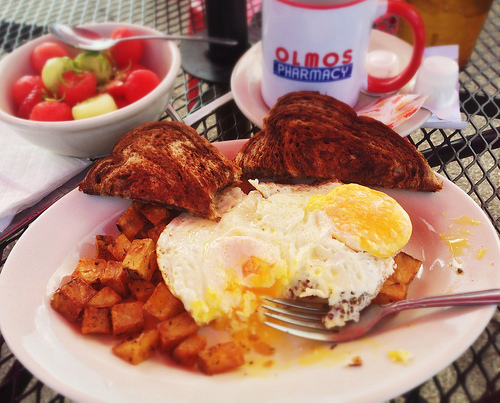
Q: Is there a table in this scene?
A: Yes, there is a table.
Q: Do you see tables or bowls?
A: Yes, there is a table.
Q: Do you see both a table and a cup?
A: Yes, there are both a table and a cup.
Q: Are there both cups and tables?
A: Yes, there are both a table and a cup.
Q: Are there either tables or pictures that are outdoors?
A: Yes, the table is outdoors.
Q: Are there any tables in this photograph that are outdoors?
A: Yes, there is a table that is outdoors.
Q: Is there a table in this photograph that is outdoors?
A: Yes, there is a table that is outdoors.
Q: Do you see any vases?
A: No, there are no vases.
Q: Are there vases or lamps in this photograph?
A: No, there are no vases or lamps.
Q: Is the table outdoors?
A: Yes, the table is outdoors.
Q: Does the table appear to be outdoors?
A: Yes, the table is outdoors.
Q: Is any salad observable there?
A: Yes, there is salad.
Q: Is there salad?
A: Yes, there is salad.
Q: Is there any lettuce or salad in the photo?
A: Yes, there is salad.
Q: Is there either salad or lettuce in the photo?
A: Yes, there is salad.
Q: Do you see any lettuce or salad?
A: Yes, there is salad.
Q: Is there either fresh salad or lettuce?
A: Yes, there is fresh salad.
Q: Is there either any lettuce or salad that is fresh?
A: Yes, the salad is fresh.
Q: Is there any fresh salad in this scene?
A: Yes, there is fresh salad.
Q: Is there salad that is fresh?
A: Yes, there is salad that is fresh.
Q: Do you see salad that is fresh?
A: Yes, there is salad that is fresh.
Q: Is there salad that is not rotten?
A: Yes, there is fresh salad.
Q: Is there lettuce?
A: No, there is no lettuce.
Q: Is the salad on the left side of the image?
A: Yes, the salad is on the left of the image.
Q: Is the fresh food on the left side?
A: Yes, the salad is on the left of the image.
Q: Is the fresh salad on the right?
A: No, the salad is on the left of the image.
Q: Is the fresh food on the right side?
A: No, the salad is on the left of the image.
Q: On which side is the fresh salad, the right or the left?
A: The salad is on the left of the image.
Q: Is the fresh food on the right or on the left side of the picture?
A: The salad is on the left of the image.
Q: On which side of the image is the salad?
A: The salad is on the left of the image.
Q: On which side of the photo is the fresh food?
A: The salad is on the left of the image.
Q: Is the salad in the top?
A: Yes, the salad is in the top of the image.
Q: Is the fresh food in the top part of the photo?
A: Yes, the salad is in the top of the image.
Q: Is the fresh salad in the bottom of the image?
A: No, the salad is in the top of the image.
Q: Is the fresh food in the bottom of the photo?
A: No, the salad is in the top of the image.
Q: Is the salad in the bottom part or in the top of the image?
A: The salad is in the top of the image.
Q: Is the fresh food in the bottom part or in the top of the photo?
A: The salad is in the top of the image.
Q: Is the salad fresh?
A: Yes, the salad is fresh.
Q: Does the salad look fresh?
A: Yes, the salad is fresh.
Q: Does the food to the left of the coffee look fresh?
A: Yes, the salad is fresh.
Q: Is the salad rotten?
A: No, the salad is fresh.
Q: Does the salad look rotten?
A: No, the salad is fresh.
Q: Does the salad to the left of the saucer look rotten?
A: No, the salad is fresh.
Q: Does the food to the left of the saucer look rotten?
A: No, the salad is fresh.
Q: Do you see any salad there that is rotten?
A: No, there is salad but it is fresh.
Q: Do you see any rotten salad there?
A: No, there is salad but it is fresh.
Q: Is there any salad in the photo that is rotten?
A: No, there is salad but it is fresh.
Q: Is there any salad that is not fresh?
A: No, there is salad but it is fresh.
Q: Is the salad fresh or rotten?
A: The salad is fresh.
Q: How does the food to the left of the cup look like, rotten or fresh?
A: The salad is fresh.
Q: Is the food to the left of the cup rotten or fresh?
A: The salad is fresh.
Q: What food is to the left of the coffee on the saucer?
A: The food is salad.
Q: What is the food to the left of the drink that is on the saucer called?
A: The food is salad.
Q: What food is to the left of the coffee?
A: The food is salad.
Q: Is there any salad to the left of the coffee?
A: Yes, there is salad to the left of the coffee.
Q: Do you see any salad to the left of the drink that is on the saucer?
A: Yes, there is salad to the left of the coffee.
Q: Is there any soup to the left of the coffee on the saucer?
A: No, there is salad to the left of the coffee.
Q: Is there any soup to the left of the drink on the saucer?
A: No, there is salad to the left of the coffee.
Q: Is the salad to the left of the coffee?
A: Yes, the salad is to the left of the coffee.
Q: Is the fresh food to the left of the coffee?
A: Yes, the salad is to the left of the coffee.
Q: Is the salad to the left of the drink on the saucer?
A: Yes, the salad is to the left of the coffee.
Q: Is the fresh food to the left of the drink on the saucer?
A: Yes, the salad is to the left of the coffee.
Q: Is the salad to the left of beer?
A: No, the salad is to the left of the coffee.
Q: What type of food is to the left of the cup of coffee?
A: The food is salad.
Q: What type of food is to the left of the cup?
A: The food is salad.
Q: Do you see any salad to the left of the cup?
A: Yes, there is salad to the left of the cup.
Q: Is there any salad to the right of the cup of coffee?
A: No, the salad is to the left of the cup.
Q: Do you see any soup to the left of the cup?
A: No, there is salad to the left of the cup.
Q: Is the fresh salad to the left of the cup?
A: Yes, the salad is to the left of the cup.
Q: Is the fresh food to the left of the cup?
A: Yes, the salad is to the left of the cup.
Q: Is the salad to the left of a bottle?
A: No, the salad is to the left of the cup.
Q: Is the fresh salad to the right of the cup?
A: No, the salad is to the left of the cup.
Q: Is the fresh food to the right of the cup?
A: No, the salad is to the left of the cup.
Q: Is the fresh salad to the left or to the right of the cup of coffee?
A: The salad is to the left of the cup.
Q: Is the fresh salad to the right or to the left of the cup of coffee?
A: The salad is to the left of the cup.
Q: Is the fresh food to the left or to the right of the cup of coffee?
A: The salad is to the left of the cup.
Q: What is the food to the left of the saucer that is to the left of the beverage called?
A: The food is salad.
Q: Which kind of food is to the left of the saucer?
A: The food is salad.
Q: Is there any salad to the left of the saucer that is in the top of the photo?
A: Yes, there is salad to the left of the saucer.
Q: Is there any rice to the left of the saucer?
A: No, there is salad to the left of the saucer.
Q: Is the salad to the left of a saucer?
A: Yes, the salad is to the left of a saucer.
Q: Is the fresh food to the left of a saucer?
A: Yes, the salad is to the left of a saucer.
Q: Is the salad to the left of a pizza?
A: No, the salad is to the left of a saucer.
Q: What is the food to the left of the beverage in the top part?
A: The food is salad.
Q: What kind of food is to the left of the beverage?
A: The food is salad.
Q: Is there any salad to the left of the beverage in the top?
A: Yes, there is salad to the left of the beverage.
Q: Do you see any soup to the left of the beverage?
A: No, there is salad to the left of the beverage.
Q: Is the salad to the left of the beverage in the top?
A: Yes, the salad is to the left of the beverage.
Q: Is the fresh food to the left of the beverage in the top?
A: Yes, the salad is to the left of the beverage.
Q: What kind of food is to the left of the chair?
A: The food is salad.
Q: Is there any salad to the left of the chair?
A: Yes, there is salad to the left of the chair.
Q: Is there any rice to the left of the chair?
A: No, there is salad to the left of the chair.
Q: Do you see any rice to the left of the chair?
A: No, there is salad to the left of the chair.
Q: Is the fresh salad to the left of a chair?
A: Yes, the salad is to the left of a chair.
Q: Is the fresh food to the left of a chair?
A: Yes, the salad is to the left of a chair.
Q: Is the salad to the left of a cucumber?
A: No, the salad is to the left of a chair.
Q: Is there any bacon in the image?
A: No, there is no bacon.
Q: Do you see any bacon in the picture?
A: No, there is no bacon.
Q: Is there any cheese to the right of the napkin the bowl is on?
A: No, there is breakfast to the right of the napkin.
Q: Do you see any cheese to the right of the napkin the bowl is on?
A: No, there is breakfast to the right of the napkin.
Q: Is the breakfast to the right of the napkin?
A: Yes, the breakfast is to the right of the napkin.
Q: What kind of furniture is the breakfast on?
A: The breakfast is on the table.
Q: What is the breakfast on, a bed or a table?
A: The breakfast is on a table.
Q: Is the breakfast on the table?
A: Yes, the breakfast is on the table.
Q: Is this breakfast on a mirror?
A: No, the breakfast is on the table.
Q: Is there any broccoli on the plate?
A: No, there is breakfast on the plate.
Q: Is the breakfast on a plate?
A: Yes, the breakfast is on a plate.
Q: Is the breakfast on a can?
A: No, the breakfast is on a plate.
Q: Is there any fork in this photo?
A: Yes, there is a fork.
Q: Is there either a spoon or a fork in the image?
A: Yes, there is a fork.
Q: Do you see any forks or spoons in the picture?
A: Yes, there is a fork.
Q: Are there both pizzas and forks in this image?
A: No, there is a fork but no pizzas.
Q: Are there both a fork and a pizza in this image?
A: No, there is a fork but no pizzas.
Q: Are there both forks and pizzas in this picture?
A: No, there is a fork but no pizzas.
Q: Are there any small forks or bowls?
A: Yes, there is a small fork.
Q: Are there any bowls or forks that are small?
A: Yes, the fork is small.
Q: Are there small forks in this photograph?
A: Yes, there is a small fork.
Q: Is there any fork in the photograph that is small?
A: Yes, there is a fork that is small.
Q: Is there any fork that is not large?
A: Yes, there is a small fork.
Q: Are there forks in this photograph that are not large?
A: Yes, there is a small fork.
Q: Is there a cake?
A: No, there are no cakes.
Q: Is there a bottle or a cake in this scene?
A: No, there are no cakes or bottles.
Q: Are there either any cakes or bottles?
A: No, there are no cakes or bottles.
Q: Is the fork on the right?
A: Yes, the fork is on the right of the image.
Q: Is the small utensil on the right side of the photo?
A: Yes, the fork is on the right of the image.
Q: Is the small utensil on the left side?
A: No, the fork is on the right of the image.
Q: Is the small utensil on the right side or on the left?
A: The fork is on the right of the image.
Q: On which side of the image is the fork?
A: The fork is on the right of the image.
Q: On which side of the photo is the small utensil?
A: The fork is on the right of the image.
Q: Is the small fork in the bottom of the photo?
A: Yes, the fork is in the bottom of the image.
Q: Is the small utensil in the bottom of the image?
A: Yes, the fork is in the bottom of the image.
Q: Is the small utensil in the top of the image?
A: No, the fork is in the bottom of the image.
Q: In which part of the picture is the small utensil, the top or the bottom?
A: The fork is in the bottom of the image.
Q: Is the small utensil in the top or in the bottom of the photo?
A: The fork is in the bottom of the image.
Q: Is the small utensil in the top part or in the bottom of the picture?
A: The fork is in the bottom of the image.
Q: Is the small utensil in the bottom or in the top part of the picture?
A: The fork is in the bottom of the image.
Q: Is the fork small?
A: Yes, the fork is small.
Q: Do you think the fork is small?
A: Yes, the fork is small.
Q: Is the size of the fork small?
A: Yes, the fork is small.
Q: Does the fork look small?
A: Yes, the fork is small.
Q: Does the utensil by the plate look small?
A: Yes, the fork is small.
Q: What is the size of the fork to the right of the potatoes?
A: The fork is small.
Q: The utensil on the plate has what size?
A: The fork is small.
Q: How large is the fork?
A: The fork is small.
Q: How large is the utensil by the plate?
A: The fork is small.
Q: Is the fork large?
A: No, the fork is small.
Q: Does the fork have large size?
A: No, the fork is small.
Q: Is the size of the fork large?
A: No, the fork is small.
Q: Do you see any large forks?
A: No, there is a fork but it is small.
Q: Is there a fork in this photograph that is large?
A: No, there is a fork but it is small.